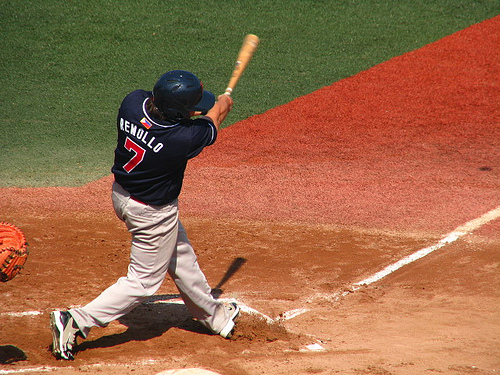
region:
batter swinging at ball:
[56, 62, 281, 332]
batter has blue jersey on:
[97, 84, 199, 211]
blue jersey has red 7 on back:
[113, 127, 147, 174]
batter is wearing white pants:
[71, 167, 216, 304]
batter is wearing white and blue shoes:
[27, 290, 102, 363]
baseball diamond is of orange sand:
[265, 120, 405, 235]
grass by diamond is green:
[30, 90, 95, 155]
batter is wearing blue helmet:
[146, 73, 200, 103]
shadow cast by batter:
[129, 258, 279, 352]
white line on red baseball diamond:
[406, 198, 476, 356]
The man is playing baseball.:
[43, 22, 345, 368]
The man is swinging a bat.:
[129, 22, 279, 155]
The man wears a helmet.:
[136, 60, 234, 122]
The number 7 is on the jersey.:
[103, 133, 161, 183]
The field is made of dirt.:
[2, 221, 499, 373]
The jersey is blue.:
[93, 88, 229, 213]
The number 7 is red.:
[108, 131, 153, 184]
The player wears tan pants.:
[63, 181, 235, 341]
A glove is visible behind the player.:
[0, 209, 44, 292]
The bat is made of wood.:
[198, 25, 274, 118]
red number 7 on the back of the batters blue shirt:
[116, 128, 146, 178]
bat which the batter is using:
[219, 31, 259, 96]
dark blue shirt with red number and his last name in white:
[109, 85, 221, 207]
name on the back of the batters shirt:
[115, 115, 164, 155]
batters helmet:
[149, 65, 216, 113]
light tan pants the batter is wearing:
[67, 179, 224, 333]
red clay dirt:
[307, 108, 471, 296]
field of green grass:
[35, 20, 192, 49]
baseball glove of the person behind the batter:
[0, 220, 30, 282]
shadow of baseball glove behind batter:
[0, 344, 30, 369]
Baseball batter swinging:
[46, 68, 242, 361]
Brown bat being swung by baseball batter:
[220, 30, 260, 115]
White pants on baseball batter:
[70, 193, 235, 335]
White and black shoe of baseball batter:
[47, 307, 77, 358]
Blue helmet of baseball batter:
[150, 66, 215, 119]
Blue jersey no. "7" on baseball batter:
[108, 90, 214, 205]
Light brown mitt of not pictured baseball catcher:
[0, 218, 30, 283]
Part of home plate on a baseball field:
[148, 363, 226, 373]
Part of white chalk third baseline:
[272, 201, 497, 321]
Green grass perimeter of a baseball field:
[1, 2, 498, 191]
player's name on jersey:
[110, 117, 167, 152]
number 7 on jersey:
[111, 138, 158, 180]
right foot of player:
[44, 310, 87, 371]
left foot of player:
[203, 290, 254, 357]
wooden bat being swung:
[224, 33, 277, 118]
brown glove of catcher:
[0, 219, 47, 291]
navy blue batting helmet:
[148, 67, 214, 123]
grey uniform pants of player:
[102, 180, 220, 320]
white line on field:
[381, 247, 439, 293]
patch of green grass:
[283, 23, 318, 74]